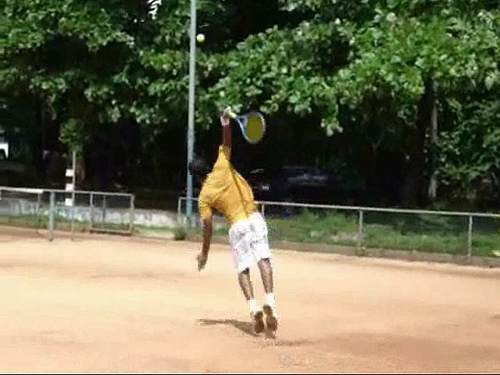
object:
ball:
[196, 33, 205, 42]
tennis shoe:
[250, 301, 281, 334]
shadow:
[197, 318, 260, 336]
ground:
[0, 232, 500, 372]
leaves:
[319, 117, 343, 138]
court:
[0, 187, 499, 375]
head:
[188, 155, 208, 177]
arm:
[198, 203, 212, 256]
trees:
[0, 0, 500, 205]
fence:
[0, 186, 500, 268]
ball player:
[189, 106, 281, 338]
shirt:
[198, 143, 258, 229]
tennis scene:
[0, 33, 497, 371]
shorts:
[228, 212, 273, 275]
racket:
[226, 111, 267, 144]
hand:
[220, 110, 232, 128]